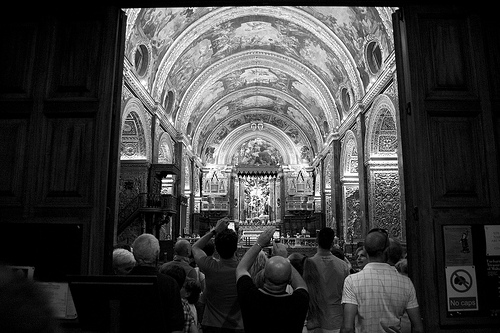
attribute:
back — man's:
[249, 257, 308, 324]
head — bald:
[260, 251, 294, 287]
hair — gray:
[130, 231, 165, 262]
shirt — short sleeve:
[342, 260, 416, 324]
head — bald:
[260, 252, 295, 292]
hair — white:
[129, 232, 161, 259]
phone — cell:
[269, 226, 281, 238]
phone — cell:
[228, 222, 234, 232]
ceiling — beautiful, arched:
[115, 13, 400, 164]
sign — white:
[443, 263, 481, 318]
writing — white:
[448, 293, 478, 313]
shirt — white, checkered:
[342, 260, 425, 330]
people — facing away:
[99, 215, 433, 327]